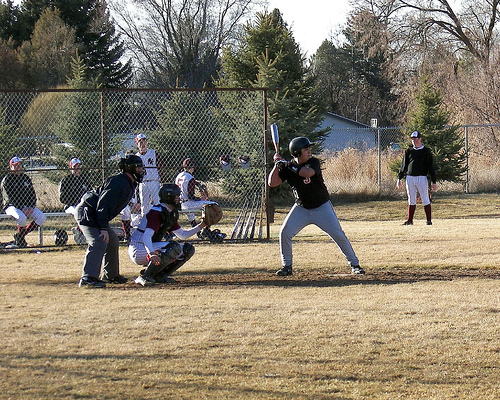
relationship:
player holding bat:
[266, 134, 366, 277] [270, 123, 283, 173]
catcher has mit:
[127, 182, 204, 287] [202, 202, 224, 225]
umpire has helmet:
[72, 154, 146, 289] [118, 155, 147, 184]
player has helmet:
[266, 134, 366, 277] [288, 136, 315, 156]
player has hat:
[136, 132, 161, 217] [135, 132, 149, 141]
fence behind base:
[0, 86, 270, 252] [323, 271, 367, 278]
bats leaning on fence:
[229, 186, 265, 241] [0, 86, 270, 252]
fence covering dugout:
[0, 86, 270, 252] [1, 198, 268, 246]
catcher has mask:
[127, 182, 204, 287] [159, 181, 183, 213]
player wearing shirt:
[266, 134, 366, 277] [274, 155, 330, 210]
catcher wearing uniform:
[127, 182, 204, 287] [127, 204, 201, 266]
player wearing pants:
[266, 134, 366, 277] [279, 199, 361, 266]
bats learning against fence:
[229, 186, 265, 241] [0, 86, 270, 252]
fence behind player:
[0, 86, 270, 252] [266, 134, 366, 277]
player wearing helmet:
[266, 134, 366, 277] [288, 136, 315, 156]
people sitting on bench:
[1, 134, 219, 248] [0, 210, 205, 244]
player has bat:
[266, 134, 366, 277] [270, 123, 283, 173]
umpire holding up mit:
[72, 154, 146, 289] [202, 202, 224, 225]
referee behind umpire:
[72, 154, 146, 289] [127, 182, 204, 287]